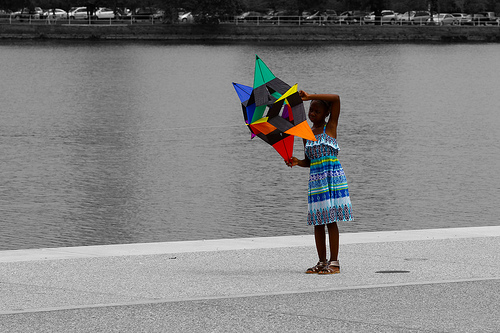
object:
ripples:
[17, 136, 153, 205]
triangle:
[271, 135, 295, 169]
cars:
[477, 11, 499, 21]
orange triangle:
[284, 119, 318, 142]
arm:
[312, 93, 341, 138]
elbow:
[328, 93, 340, 104]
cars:
[40, 7, 68, 21]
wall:
[250, 26, 339, 35]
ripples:
[61, 45, 169, 116]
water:
[0, 169, 205, 250]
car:
[8, 5, 45, 20]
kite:
[231, 53, 319, 169]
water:
[356, 47, 499, 99]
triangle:
[252, 54, 276, 90]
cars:
[178, 9, 218, 24]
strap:
[321, 122, 328, 134]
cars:
[423, 13, 459, 26]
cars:
[394, 10, 432, 25]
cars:
[261, 10, 304, 25]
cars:
[334, 9, 371, 24]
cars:
[302, 8, 338, 22]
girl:
[283, 89, 341, 274]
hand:
[284, 156, 299, 166]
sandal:
[303, 258, 328, 273]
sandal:
[316, 259, 341, 274]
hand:
[299, 89, 311, 102]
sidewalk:
[0, 225, 500, 332]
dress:
[302, 117, 355, 226]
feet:
[317, 263, 340, 274]